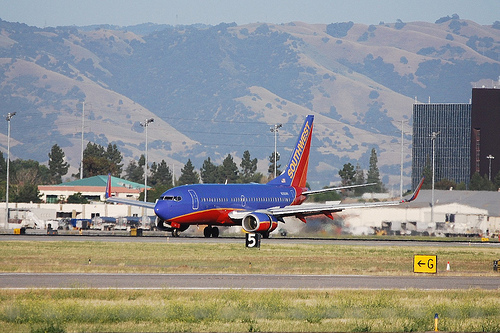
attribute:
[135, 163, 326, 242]
airplane — large 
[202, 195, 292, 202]
windows — small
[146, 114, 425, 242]
plane — blue, Red 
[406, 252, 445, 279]
sign — yellow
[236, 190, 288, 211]
windows — small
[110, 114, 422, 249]
airplane — large, passenger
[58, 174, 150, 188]
roof — green 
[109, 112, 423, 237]
airplane — blue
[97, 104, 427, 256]
plane — large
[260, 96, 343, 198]
plane's tail — blue, orange, red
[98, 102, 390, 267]
plane — large, passenger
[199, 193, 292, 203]
windows — small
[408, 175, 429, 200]
tip — red 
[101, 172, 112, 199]
tip — red 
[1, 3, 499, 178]
hills — large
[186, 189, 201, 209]
door — large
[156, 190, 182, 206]
window — large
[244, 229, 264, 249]
sign — black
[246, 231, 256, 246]
number — white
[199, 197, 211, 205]
window — small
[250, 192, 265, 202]
window — small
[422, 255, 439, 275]
5 — number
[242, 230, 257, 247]
number — black